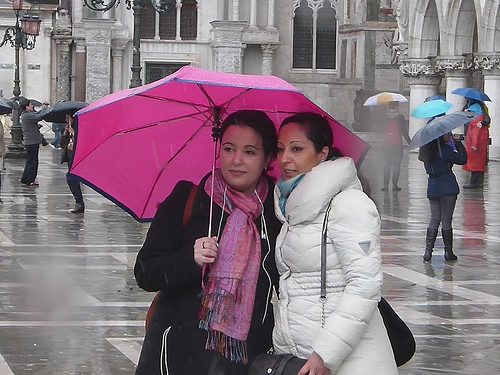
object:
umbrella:
[67, 63, 374, 225]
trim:
[64, 172, 154, 224]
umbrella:
[363, 92, 409, 106]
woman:
[272, 111, 398, 374]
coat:
[273, 160, 400, 375]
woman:
[133, 110, 283, 374]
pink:
[231, 233, 243, 252]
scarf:
[201, 171, 269, 363]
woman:
[421, 131, 469, 263]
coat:
[422, 142, 468, 198]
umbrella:
[409, 113, 476, 149]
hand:
[192, 233, 220, 268]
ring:
[202, 240, 209, 250]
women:
[132, 110, 396, 375]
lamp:
[1, 1, 42, 159]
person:
[463, 103, 490, 189]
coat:
[462, 117, 490, 172]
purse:
[246, 348, 326, 374]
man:
[17, 99, 50, 187]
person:
[382, 102, 412, 193]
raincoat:
[274, 157, 396, 372]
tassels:
[199, 324, 252, 366]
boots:
[423, 227, 458, 262]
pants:
[20, 143, 41, 185]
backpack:
[386, 120, 403, 150]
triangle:
[357, 239, 371, 256]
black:
[147, 249, 174, 276]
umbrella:
[451, 86, 492, 103]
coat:
[378, 115, 411, 153]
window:
[288, 1, 342, 74]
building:
[56, 2, 407, 130]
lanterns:
[19, 14, 43, 36]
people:
[378, 102, 490, 265]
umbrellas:
[364, 88, 491, 152]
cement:
[89, 29, 112, 83]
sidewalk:
[4, 220, 103, 373]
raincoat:
[465, 116, 489, 172]